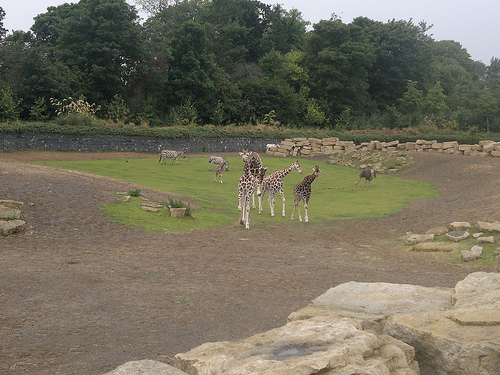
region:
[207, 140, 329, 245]
herd of giraffes in park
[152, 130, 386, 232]
giraffes zebra and gazelle in park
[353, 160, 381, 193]
grey gazelle running in park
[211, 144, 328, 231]
brown and white giraffes walking in park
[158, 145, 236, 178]
two black and white zebras walking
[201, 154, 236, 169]
one zebra grazing in park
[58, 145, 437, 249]
large green grassy patch with animals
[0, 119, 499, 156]
brick and stone wall bordering trees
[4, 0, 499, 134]
green trees bordering park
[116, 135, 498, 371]
large grey stone boulders inside park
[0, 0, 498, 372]
An outdoor area with animals.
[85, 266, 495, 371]
Tan colored stone boulders.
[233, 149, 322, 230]
A group of four giraffes.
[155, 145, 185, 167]
A zebra on the grass.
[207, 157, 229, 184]
A baby giraffe on the grass.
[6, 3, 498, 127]
A area of trees.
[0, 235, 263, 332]
The grass-less area of dirt.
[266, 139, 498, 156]
A pile of stones.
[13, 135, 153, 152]
A dark stone wall.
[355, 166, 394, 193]
An animal on the grass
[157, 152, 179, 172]
the grass is green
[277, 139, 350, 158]
the rocks are brown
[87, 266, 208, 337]
the ground is brown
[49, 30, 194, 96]
the trees are green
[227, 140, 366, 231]
there are giraffes on the field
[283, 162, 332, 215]
the giraffe is brown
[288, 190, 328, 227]
the giraffe has four legs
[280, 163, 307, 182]
the giraffe has long neck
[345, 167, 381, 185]
the animal is eating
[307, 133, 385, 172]
the rocks are rectangle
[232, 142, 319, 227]
these are some giraffes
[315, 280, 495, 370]
these are rocks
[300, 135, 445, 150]
the stone blocks are big in size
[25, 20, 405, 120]
there are several trees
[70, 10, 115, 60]
the tree leaves are green in color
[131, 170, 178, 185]
this is some grass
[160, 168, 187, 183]
the grass is green in color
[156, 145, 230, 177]
there are some zebras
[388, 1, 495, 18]
this is the sky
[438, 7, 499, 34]
the sky is clear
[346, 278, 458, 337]
part of some stones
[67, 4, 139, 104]
part of a green tree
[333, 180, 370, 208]
part of a green ground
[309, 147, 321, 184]
head of a giraffe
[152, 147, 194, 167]
part of a zebra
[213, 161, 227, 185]
part of a small giraffe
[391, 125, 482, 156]
pile of many bricks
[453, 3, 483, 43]
section of the sky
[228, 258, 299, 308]
part of the dry ground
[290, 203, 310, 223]
legs of a giraffe